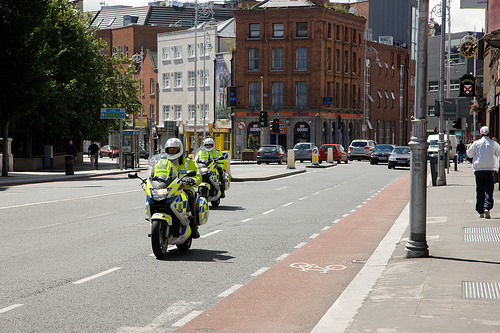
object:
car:
[318, 144, 348, 164]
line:
[313, 192, 320, 195]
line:
[262, 209, 275, 214]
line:
[242, 218, 253, 223]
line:
[200, 229, 222, 237]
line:
[73, 267, 123, 284]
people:
[141, 137, 226, 238]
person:
[456, 139, 466, 164]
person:
[193, 137, 226, 198]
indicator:
[290, 262, 347, 274]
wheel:
[198, 186, 208, 202]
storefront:
[182, 120, 233, 161]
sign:
[184, 124, 209, 132]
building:
[86, 7, 160, 158]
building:
[157, 16, 236, 159]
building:
[231, 5, 365, 161]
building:
[365, 40, 412, 146]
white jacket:
[465, 136, 499, 172]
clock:
[460, 40, 477, 58]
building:
[458, 0, 500, 140]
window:
[248, 49, 259, 72]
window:
[296, 22, 307, 38]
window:
[272, 23, 283, 38]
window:
[271, 48, 285, 70]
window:
[271, 81, 283, 107]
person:
[144, 137, 202, 238]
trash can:
[64, 155, 75, 175]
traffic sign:
[237, 121, 246, 130]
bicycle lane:
[171, 171, 410, 333]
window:
[295, 46, 307, 70]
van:
[426, 134, 457, 159]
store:
[232, 112, 365, 160]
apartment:
[237, 73, 322, 110]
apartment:
[233, 40, 321, 71]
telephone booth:
[121, 129, 140, 167]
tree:
[1, 2, 145, 154]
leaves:
[27, 0, 140, 142]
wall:
[0, 160, 86, 168]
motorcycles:
[128, 157, 232, 257]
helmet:
[164, 138, 184, 161]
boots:
[191, 229, 199, 239]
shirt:
[88, 144, 100, 155]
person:
[466, 126, 499, 219]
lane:
[244, 296, 347, 325]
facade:
[163, 41, 209, 118]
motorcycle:
[128, 170, 211, 258]